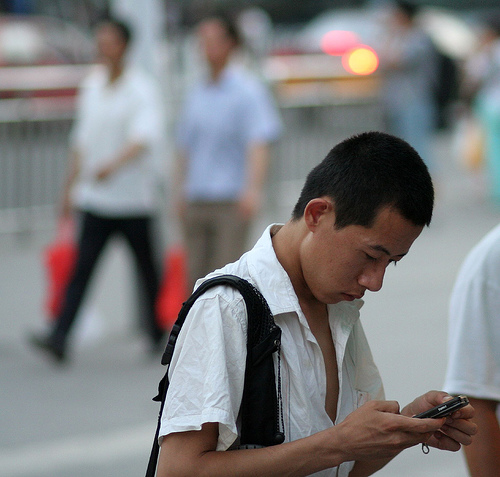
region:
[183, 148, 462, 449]
man is looking at the phone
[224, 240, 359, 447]
the shirt is half unbottoned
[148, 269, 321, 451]
the bag is on the shoulder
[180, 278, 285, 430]
bag is black incolo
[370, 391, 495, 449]
cell phonr is black in color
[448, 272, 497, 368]
the t shirt is white in color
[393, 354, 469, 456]
man holding a cell phone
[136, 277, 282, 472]
man wearing a backpack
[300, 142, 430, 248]
man with black hair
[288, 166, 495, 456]
man looking at his cellphone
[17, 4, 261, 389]
Two people walking in the street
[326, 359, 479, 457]
cellphone in the man hands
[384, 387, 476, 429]
black and silver cell phone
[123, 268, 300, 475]
black bag shoulder strap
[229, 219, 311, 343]
white collar of shirt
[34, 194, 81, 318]
blurred orange bag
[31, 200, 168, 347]
blurred pair of black pants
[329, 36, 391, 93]
round orange blurred spot light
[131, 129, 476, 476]
young man looking down at cell phone in hand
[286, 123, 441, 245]
head of black hair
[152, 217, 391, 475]
white short sleeve shirt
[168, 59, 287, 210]
blurred blue short sleeve shirt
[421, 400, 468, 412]
a mobile phone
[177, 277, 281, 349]
the strap of a bag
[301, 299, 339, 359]
the chest of a man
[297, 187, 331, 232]
the ear of a man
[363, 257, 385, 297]
the nose of a man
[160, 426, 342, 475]
the hand of a man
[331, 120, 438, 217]
the black hair on the head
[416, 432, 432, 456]
the piece of strap on the phone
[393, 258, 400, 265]
eye lashes of a man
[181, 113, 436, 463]
a man looking at his phone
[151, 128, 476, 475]
a man in a white shirt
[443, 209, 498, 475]
a person in a white shirt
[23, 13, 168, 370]
a person in a white shirt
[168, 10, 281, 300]
a person in a blue shirt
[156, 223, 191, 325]
a large red bag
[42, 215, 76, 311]
a large red bag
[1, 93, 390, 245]
some long metal rails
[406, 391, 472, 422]
A black cellphone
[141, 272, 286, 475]
a black bag on a person's shoulder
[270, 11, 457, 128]
a car on the road